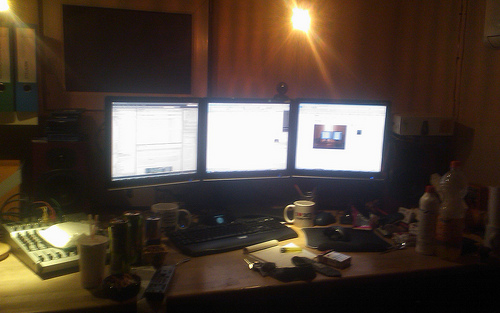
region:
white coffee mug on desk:
[283, 198, 318, 228]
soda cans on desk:
[109, 211, 163, 260]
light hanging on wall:
[281, 3, 318, 44]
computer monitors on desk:
[112, 101, 391, 185]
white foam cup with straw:
[76, 217, 109, 295]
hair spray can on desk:
[416, 182, 440, 256]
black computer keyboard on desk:
[169, 218, 297, 255]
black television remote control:
[144, 262, 176, 304]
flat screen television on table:
[39, 1, 211, 116]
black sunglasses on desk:
[321, 210, 353, 227]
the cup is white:
[75, 234, 115, 290]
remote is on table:
[142, 262, 192, 304]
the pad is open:
[252, 237, 297, 277]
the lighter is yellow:
[279, 245, 305, 255]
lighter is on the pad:
[250, 236, 307, 271]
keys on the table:
[241, 255, 268, 273]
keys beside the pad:
[250, 237, 308, 274]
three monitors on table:
[110, 90, 385, 191]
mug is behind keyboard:
[147, 196, 261, 244]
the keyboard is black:
[178, 220, 279, 245]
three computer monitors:
[91, 92, 416, 192]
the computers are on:
[101, 90, 393, 190]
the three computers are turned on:
[102, 91, 398, 197]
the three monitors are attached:
[96, 90, 392, 190]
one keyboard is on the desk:
[164, 212, 301, 257]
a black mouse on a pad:
[304, 222, 391, 254]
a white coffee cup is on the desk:
[283, 196, 317, 228]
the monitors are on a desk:
[7, 86, 499, 297]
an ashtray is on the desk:
[100, 266, 141, 296]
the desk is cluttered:
[22, 162, 485, 295]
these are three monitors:
[111, 100, 387, 178]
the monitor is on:
[319, 116, 369, 168]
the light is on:
[282, 2, 322, 34]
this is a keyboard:
[210, 216, 257, 246]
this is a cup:
[290, 196, 315, 219]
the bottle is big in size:
[436, 166, 473, 257]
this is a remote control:
[145, 260, 180, 300]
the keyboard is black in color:
[215, 225, 240, 247]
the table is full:
[176, 205, 381, 279]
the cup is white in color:
[289, 200, 316, 225]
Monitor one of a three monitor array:
[100, 91, 204, 185]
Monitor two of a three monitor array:
[202, 97, 292, 178]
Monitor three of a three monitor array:
[292, 95, 394, 187]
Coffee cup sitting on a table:
[285, 200, 320, 230]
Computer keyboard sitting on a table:
[175, 219, 298, 249]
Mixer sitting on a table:
[1, 203, 93, 279]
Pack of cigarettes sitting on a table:
[315, 246, 355, 267]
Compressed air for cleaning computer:
[412, 181, 439, 261]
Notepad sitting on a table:
[242, 240, 318, 277]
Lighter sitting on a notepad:
[276, 243, 303, 253]